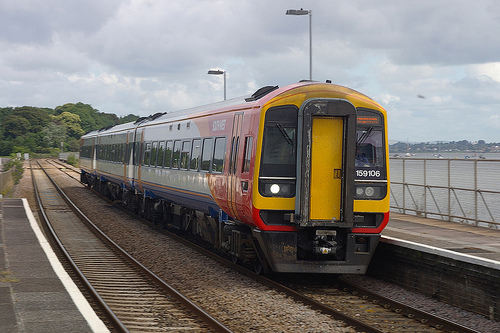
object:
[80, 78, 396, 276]
train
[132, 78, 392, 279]
car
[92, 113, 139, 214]
car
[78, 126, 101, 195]
car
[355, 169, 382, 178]
numbers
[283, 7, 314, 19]
light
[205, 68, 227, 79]
light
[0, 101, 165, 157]
trees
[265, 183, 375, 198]
headlights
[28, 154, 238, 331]
track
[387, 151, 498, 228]
water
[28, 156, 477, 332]
train tracks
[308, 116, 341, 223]
door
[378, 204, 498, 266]
walkway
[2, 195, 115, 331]
walkway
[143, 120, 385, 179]
window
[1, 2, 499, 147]
clouds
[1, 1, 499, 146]
sky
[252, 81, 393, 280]
train front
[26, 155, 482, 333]
rails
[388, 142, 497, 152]
land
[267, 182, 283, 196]
light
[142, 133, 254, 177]
windows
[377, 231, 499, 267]
line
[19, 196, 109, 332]
line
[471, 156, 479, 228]
pole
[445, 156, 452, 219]
pole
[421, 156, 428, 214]
pole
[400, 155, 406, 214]
pole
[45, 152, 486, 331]
tracks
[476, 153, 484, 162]
boat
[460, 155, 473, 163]
boat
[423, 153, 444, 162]
boat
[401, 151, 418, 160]
boat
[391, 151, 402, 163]
boat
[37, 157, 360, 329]
gravel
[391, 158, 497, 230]
fence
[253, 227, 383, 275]
plate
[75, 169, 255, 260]
bottom